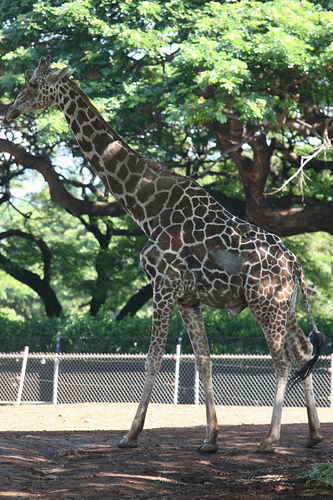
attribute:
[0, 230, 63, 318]
trunk — brown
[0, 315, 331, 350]
bushes — green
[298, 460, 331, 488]
grass — green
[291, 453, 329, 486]
patch — green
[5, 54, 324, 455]
giraffe — front left, standing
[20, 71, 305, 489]
giraffe — alone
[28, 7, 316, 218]
trees — summer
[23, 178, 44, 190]
sky — blue, light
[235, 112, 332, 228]
branch — dead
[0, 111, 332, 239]
branch — large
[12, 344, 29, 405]
pole — metal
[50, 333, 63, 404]
pole — metal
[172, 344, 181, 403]
pole — metal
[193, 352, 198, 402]
pole — metal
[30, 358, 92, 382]
fence — small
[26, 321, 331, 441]
fence — chain link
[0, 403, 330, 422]
gravel — brown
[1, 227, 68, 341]
tree — large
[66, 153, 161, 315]
tree — large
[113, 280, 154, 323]
tree — large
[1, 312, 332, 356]
bushes — green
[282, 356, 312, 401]
hair — long, black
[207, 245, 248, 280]
spot — gray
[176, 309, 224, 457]
leg — long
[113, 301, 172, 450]
leg — long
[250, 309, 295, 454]
leg — long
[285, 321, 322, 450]
leg — long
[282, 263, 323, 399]
tail — black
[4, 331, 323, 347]
wire — barbed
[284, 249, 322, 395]
tail — hind tail